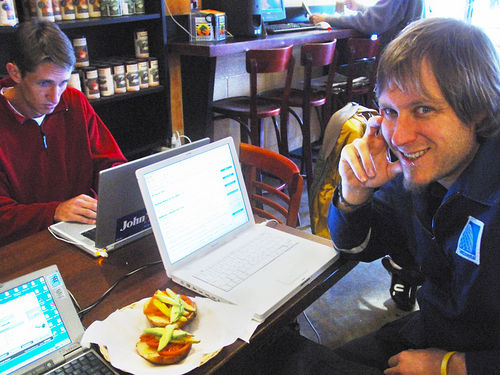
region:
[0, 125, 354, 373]
three laptops on a table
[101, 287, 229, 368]
two pieces of toast on a plate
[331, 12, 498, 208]
a man smiling for the photo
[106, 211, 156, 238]
black sticker says john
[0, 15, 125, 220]
man wearing a red shirt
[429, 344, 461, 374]
a yellow band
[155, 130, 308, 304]
a laptop with the screen on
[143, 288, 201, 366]
two pieces of toast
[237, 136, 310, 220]
back of a wooden chair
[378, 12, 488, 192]
a man with a lip piercing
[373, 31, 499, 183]
a man with long hair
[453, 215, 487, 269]
a logo on a jacket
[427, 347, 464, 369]
yellow band on a person's wrist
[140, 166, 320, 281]
a white laptop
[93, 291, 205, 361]
food on a plate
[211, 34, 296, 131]
a wooden bar stool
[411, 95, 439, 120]
the eye of a person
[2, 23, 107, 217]
a man in a red sweatshirt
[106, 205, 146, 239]
a sticker on a laptop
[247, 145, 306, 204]
a wooden chair back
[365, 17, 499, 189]
Man's face with lip piercing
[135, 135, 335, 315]
An Apple brand laptop computer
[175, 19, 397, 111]
Three barstools behind the bar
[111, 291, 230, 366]
An open-face sandwich with avocado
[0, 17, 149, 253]
Man wearing a red sweatshirt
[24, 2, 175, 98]
Jars of looseleaf tea on a shelf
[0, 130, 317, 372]
Three open laptop computers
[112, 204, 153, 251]
A political sticker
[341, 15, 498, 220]
A man smiling at the camera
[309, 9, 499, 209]
A man touching his face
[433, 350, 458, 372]
a yellow rubber wrist band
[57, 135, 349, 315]
two silver laptops turned on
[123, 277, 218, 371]
a healthy pair of snacks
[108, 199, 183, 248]
a black sticker on computer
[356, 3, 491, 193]
a man with longer hair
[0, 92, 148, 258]
a red pull over jacket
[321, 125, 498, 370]
a blue zip up jacket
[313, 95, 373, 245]
a yellow rain jacket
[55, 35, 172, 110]
a set of tea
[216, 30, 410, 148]
a few wooden chairs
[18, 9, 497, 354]
this is a coffee shop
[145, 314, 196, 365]
this is a burger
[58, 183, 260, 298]
this is are laptops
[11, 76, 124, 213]
a guy on a laptop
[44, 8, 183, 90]
neatly arrangements on the shelf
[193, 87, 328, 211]
wooden chairs in the background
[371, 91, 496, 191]
a guy is smiling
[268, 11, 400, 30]
a guy sitted on the counter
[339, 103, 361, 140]
this is a coat on a chair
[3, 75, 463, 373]
what a lovely photo